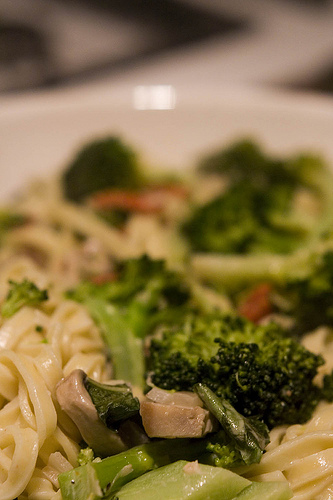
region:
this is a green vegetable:
[58, 437, 150, 486]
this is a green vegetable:
[194, 387, 277, 468]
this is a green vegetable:
[80, 373, 143, 427]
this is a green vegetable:
[79, 272, 157, 359]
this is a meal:
[20, 238, 307, 491]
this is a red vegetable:
[239, 278, 268, 320]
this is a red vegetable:
[87, 179, 209, 233]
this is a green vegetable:
[4, 281, 57, 321]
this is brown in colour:
[133, 385, 218, 457]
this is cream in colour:
[5, 334, 62, 480]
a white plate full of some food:
[16, 99, 310, 494]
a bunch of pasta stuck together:
[7, 336, 69, 425]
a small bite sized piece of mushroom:
[57, 372, 103, 438]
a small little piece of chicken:
[142, 397, 212, 435]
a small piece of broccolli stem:
[63, 450, 184, 485]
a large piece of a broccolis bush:
[213, 339, 300, 412]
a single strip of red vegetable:
[84, 183, 178, 216]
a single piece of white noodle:
[264, 435, 327, 454]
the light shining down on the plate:
[130, 81, 170, 113]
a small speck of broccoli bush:
[58, 468, 86, 491]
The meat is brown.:
[136, 397, 213, 439]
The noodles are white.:
[7, 398, 49, 451]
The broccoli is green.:
[224, 355, 294, 413]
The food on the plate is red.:
[238, 282, 266, 319]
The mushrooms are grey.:
[44, 373, 91, 429]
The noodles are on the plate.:
[7, 365, 49, 419]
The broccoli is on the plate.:
[217, 343, 295, 391]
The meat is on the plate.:
[133, 395, 210, 438]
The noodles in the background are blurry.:
[42, 229, 105, 264]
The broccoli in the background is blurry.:
[197, 201, 297, 255]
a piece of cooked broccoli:
[150, 309, 320, 452]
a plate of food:
[3, 77, 329, 497]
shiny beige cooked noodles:
[7, 315, 60, 419]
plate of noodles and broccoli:
[4, 111, 321, 499]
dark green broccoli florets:
[214, 342, 292, 406]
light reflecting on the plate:
[126, 80, 180, 114]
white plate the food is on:
[4, 76, 331, 176]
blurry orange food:
[92, 180, 189, 218]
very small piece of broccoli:
[0, 271, 51, 325]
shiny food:
[2, 172, 331, 493]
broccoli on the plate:
[222, 361, 249, 383]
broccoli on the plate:
[151, 469, 196, 490]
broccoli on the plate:
[268, 364, 301, 398]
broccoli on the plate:
[207, 214, 253, 242]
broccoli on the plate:
[101, 390, 133, 435]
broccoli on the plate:
[13, 281, 38, 299]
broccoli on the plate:
[136, 260, 168, 288]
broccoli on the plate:
[137, 271, 188, 318]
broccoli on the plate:
[173, 328, 295, 414]